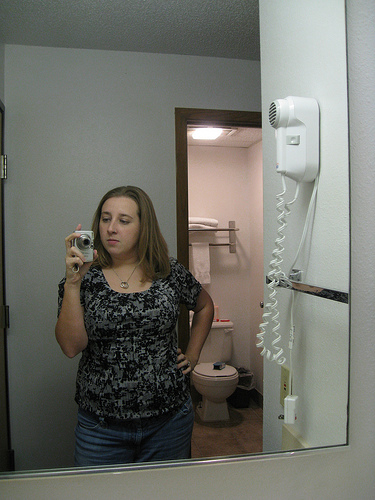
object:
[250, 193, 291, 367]
wire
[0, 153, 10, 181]
hinge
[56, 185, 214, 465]
woman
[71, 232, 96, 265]
camera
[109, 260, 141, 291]
necklace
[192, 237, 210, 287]
hand towel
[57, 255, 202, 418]
blouse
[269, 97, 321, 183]
hair dryer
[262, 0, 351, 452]
wall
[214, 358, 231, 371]
box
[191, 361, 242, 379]
toilet cover